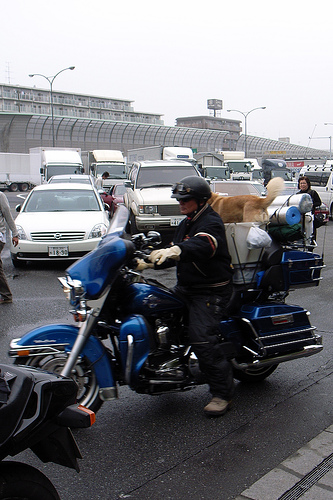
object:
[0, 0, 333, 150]
sky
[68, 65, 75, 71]
street lamp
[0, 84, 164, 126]
building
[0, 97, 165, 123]
balconies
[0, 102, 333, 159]
stadium wall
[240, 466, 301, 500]
single brick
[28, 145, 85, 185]
tractor trailors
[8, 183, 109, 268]
car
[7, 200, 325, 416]
motorcycle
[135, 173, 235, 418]
man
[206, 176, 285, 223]
dog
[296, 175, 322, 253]
woman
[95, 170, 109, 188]
person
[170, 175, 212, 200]
helmet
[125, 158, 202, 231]
cars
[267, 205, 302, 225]
items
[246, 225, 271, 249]
bag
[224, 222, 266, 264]
container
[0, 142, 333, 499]
in parking lot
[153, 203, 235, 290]
jacket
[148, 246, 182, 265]
gloves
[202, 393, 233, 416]
shoes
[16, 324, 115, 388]
fender